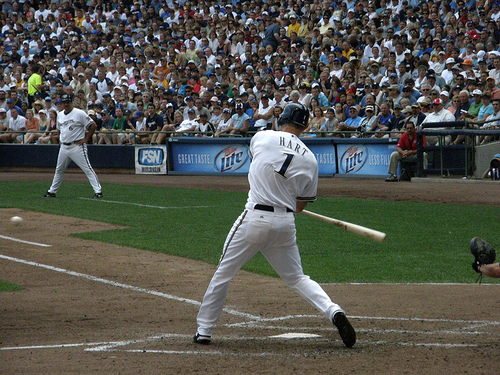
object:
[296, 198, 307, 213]
hand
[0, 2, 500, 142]
people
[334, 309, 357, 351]
cleat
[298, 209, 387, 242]
bat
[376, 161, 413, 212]
ground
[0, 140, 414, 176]
wall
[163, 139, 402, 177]
adertisment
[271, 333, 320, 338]
home plate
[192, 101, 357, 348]
person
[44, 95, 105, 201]
person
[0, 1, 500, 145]
crowd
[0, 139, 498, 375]
baseball game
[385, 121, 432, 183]
man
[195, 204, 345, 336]
pants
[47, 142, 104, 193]
pants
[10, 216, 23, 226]
ball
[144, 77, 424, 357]
action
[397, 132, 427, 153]
shirt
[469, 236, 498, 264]
catcher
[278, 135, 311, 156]
name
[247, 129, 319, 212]
jersey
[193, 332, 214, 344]
cleat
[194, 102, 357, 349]
batter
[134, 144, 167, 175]
banner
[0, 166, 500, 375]
playing field